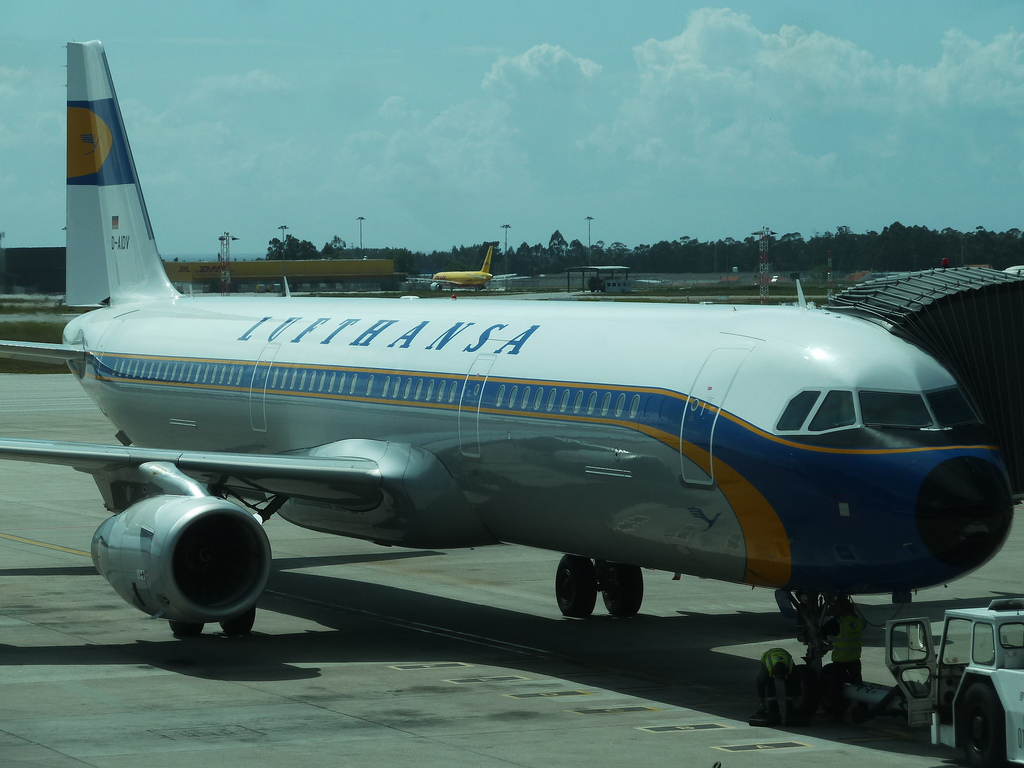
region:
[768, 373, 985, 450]
windows on the front of the plane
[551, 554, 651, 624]
wheels on the plane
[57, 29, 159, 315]
tip of the plane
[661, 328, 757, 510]
door on the plane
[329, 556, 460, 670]
shadow of the plane on the ground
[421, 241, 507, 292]
yellow plane across the runaway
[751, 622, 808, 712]
person under the plane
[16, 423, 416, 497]
wing on the plane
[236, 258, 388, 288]
building on the runaway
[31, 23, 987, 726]
Thee blue and white airplane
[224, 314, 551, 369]
the name on the blue airplane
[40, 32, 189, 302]
The tail of the blue airplane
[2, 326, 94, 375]
The back wing on the blue airplane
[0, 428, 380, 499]
The left wing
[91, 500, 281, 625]
The gray engine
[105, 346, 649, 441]
The row of windows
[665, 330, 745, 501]
The front door of the blue airplane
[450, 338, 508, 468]
The middle door of the airplane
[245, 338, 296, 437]
The back door of the airplane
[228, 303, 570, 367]
Lufthansa written on the airplane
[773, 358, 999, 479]
Cockpit area with windows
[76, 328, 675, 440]
Windows of the plane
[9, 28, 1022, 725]
An airplane at the airport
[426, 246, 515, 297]
Yellow plane in the background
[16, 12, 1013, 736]
Sunny day at the airport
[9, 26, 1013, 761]
Plane run by Lufthansa company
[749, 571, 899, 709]
Front wheels of the plane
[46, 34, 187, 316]
Airline logo on the plane's tail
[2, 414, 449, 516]
Right wing of the plane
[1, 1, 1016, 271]
White clouds in the sky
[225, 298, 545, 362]
"LUFTHANSA" written on plane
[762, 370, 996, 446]
Front windows of a plane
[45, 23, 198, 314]
Tail of an airplane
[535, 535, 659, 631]
Two black plane wheels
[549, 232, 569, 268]
A tree in the woods.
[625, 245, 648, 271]
A tree in the woods.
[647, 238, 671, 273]
A tree in the woods.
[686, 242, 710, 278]
A tree in the woods.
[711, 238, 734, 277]
A tree in the woods.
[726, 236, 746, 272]
A tree in the woods.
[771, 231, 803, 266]
A tree in the woods.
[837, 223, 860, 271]
A tree in the woods.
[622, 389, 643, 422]
window on the plane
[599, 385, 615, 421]
window on the plane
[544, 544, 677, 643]
wheels of the plane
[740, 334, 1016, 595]
nose of the plane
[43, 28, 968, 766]
it is a white and blue plane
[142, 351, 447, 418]
windows on the plane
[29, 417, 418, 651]
wing of the plane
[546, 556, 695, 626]
it is a black wheel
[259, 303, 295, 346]
letter on an airplane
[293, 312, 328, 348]
letter on an airplane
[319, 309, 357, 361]
letter on an airplane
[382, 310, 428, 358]
letter on an airplane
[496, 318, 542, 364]
letter on an airplane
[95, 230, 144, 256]
letter on an airplane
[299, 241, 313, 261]
A tree in the woods.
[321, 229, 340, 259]
A tree in the woods.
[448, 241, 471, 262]
A tree in the woods.